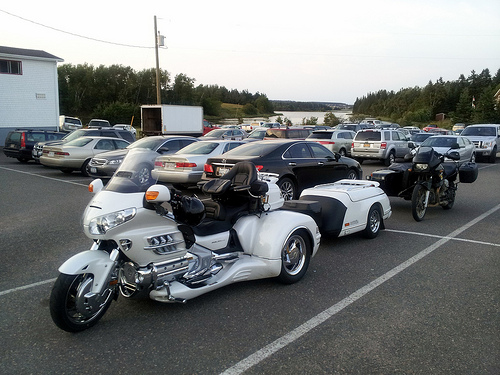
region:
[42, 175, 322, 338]
White motorcycle in parking lot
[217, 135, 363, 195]
Back right side of black car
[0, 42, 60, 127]
White building with a window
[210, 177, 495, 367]
White divider strips for parking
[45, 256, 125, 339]
Front wheel of motorcycle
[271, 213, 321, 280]
Back rear wheel of motorcycle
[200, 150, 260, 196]
Back of black car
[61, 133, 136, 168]
Right side of light colored car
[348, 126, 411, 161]
Tan colored suv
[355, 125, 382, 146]
Back windshield of tan colored car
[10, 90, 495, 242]
cars in a parking lot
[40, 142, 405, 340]
a bike with a trailer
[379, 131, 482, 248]
a dirt bike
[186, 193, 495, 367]
the parking lines are white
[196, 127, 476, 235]
a black car beside the bike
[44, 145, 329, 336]
the white bike has a black seat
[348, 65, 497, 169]
trees on the other side of the cars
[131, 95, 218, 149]
a white trailer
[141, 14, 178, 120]
a brown telephone pole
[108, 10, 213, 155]
the trailer is beside the telephone pole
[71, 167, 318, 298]
white motorcycle in photo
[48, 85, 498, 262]
many cars parked in parking lot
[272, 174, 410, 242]
motorcycle pulling white cargo holder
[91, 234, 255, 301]
silver details on white motorcycle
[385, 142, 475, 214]
black motorcycle in photograph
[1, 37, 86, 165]
white building with grey roof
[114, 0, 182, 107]
electrical pole in photograph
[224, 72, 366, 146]
pond visible in back of photograph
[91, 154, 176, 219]
orange headlights on motorcycle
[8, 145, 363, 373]
white lines in parking lot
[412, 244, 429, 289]
side of a road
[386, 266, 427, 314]
edge of a road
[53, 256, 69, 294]
part of a wheel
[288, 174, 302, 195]
part of a wheel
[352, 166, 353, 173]
wheel of a car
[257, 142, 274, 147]
window of a car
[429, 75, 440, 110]
branches of a tree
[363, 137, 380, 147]
back of a car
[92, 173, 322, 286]
The bike is white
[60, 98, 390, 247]
The cars are parked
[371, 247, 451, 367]
The ground has lines on it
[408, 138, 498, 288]
The bike is black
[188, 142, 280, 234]
The seat is leather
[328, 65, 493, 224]
The trees are green and tall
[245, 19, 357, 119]
The sky is white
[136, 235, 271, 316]
The side of the bike is metal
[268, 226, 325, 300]
The tire has a rim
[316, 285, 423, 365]
The ground is gray